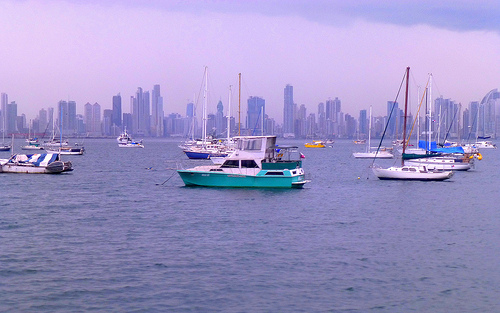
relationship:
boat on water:
[176, 66, 313, 191] [81, 188, 378, 233]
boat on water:
[176, 66, 313, 191] [10, 134, 484, 311]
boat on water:
[369, 66, 454, 181] [10, 134, 484, 311]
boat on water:
[2, 150, 74, 176] [10, 134, 484, 311]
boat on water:
[351, 149, 393, 156] [10, 134, 484, 311]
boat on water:
[183, 142, 233, 160] [10, 134, 484, 311]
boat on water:
[163, 133, 315, 202] [62, 243, 153, 300]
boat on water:
[176, 66, 313, 191] [156, 178, 331, 272]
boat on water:
[357, 65, 454, 180] [10, 134, 484, 311]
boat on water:
[42, 111, 84, 157] [206, 222, 411, 260]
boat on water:
[352, 106, 394, 160] [10, 134, 484, 311]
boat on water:
[183, 66, 234, 159] [10, 134, 484, 311]